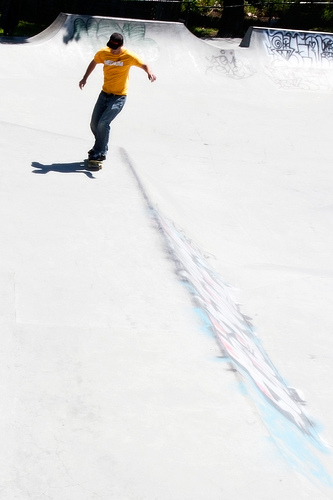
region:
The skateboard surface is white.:
[0, 12, 331, 499]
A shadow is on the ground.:
[32, 160, 99, 177]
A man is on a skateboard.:
[79, 33, 156, 169]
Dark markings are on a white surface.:
[120, 146, 324, 446]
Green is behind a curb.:
[180, 0, 332, 33]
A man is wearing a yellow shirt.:
[94, 48, 139, 96]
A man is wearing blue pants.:
[88, 92, 125, 160]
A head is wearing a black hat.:
[107, 33, 124, 54]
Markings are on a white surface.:
[72, 16, 332, 62]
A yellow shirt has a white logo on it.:
[93, 49, 139, 93]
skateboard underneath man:
[79, 144, 107, 175]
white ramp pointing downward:
[52, 227, 275, 377]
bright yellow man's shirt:
[91, 45, 149, 94]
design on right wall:
[268, 30, 318, 57]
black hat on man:
[105, 28, 132, 75]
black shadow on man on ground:
[30, 142, 92, 180]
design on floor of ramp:
[169, 243, 251, 344]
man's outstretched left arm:
[135, 50, 163, 97]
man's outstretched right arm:
[81, 55, 102, 96]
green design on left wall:
[78, 20, 113, 39]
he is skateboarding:
[38, 10, 209, 204]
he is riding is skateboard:
[56, 11, 173, 212]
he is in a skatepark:
[38, 7, 204, 214]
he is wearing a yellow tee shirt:
[84, 40, 176, 114]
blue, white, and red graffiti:
[151, 187, 326, 465]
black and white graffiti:
[253, 23, 330, 77]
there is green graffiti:
[67, 9, 160, 57]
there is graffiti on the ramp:
[67, 13, 277, 95]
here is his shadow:
[24, 140, 105, 206]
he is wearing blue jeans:
[88, 93, 146, 158]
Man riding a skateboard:
[74, 30, 158, 170]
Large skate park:
[0, 11, 332, 499]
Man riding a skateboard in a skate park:
[75, 31, 155, 171]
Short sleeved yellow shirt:
[92, 47, 142, 97]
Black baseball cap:
[106, 30, 124, 49]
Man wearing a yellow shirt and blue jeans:
[78, 32, 157, 161]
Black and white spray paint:
[261, 27, 331, 65]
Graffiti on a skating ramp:
[261, 27, 330, 66]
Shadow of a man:
[30, 157, 97, 181]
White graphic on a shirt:
[102, 58, 124, 67]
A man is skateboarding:
[63, 29, 160, 180]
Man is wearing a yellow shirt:
[91, 42, 147, 102]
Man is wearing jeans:
[73, 86, 133, 161]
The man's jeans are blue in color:
[80, 86, 131, 156]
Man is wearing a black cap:
[97, 29, 130, 59]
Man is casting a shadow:
[23, 153, 97, 187]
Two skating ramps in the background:
[32, 7, 332, 71]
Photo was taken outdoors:
[0, 2, 332, 479]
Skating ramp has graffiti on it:
[259, 25, 331, 68]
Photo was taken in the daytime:
[3, 2, 332, 488]